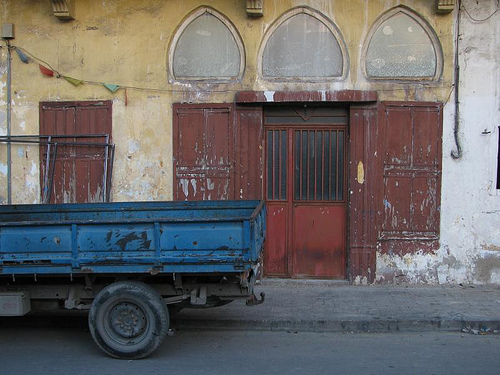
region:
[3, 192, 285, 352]
a blue cart is in the road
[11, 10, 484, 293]
the building is covered in chipped paint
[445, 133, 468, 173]
a hook hangs on the wall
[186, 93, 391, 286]
the area of the door is painted red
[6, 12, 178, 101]
part of the wall is painted yellow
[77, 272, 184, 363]
one of the carts tires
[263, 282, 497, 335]
the sidewalk is shown behind the cart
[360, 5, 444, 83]
arched shaped window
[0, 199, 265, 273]
the truck bed is blue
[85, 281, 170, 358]
the tire was black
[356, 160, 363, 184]
the paint is chipped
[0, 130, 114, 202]
chain link fencing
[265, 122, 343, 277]
a metal door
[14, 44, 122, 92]
a string of flags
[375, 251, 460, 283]
the building siding is chipped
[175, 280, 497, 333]
a gray sidewalk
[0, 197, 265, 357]
Very old pickup truck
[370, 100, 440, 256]
Shutter with fading red paint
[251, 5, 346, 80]
Oddly shaped dirty window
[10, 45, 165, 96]
Multicolored flags on a wall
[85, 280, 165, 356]
Dusty old tire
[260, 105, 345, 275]
Old red barred door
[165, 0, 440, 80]
Three odd windows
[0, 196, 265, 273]
Bed of blue truck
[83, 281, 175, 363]
a black rear truck wheel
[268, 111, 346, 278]
a rusty metal door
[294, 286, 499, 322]
a gray brick side walk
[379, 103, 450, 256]
a red wooden shutter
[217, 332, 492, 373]
a blcak top road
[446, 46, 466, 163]
a hook on a wall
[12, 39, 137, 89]
flags on a rope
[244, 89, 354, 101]
paint peeling on a door way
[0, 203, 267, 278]
a blue truck bed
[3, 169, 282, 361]
the back of a truck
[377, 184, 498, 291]
peeling paint on the building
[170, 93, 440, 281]
The red door is close.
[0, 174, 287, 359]
The blue truck is worm out.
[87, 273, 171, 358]
The tire is black and worn out.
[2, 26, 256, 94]
There is an electric line hanging.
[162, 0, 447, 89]
The windows are triangular.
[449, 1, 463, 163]
Electric line comes out the wall.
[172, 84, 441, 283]
The red door has chipped paint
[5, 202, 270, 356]
The blue truck is square.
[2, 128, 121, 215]
There are metal frames by the wall.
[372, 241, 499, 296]
The white paint on the wall is chipped away.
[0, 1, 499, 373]
a scene during the day time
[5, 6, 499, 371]
a scene outside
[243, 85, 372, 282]
a red door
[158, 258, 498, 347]
a gray concrete sidewalk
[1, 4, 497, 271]
a yellow and white wall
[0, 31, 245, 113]
multicolored banner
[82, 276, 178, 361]
a large black wheel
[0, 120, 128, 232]
silver metal poles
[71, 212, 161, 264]
a very old sheet of metal painted blue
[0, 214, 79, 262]
a very old sheet of metal painted blue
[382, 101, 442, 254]
a very old wooden door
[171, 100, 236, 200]
a very old wooden door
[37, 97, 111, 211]
a very old wooden door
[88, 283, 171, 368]
the rear wheel of a vehicle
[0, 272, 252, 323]
the chassis of a vehicle